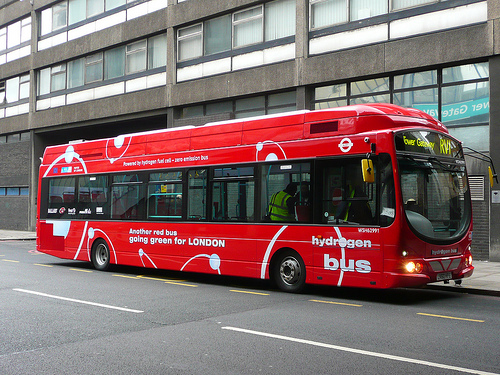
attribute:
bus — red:
[33, 115, 413, 199]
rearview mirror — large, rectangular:
[359, 156, 376, 185]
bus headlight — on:
[402, 258, 418, 274]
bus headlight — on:
[466, 254, 472, 264]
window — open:
[0, 79, 7, 105]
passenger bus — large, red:
[35, 102, 473, 291]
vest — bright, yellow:
[267, 188, 293, 221]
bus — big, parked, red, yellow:
[34, 103, 474, 293]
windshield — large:
[395, 150, 471, 242]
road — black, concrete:
[2, 240, 498, 371]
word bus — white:
[321, 251, 371, 275]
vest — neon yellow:
[266, 191, 293, 219]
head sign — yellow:
[395, 129, 464, 160]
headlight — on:
[402, 259, 418, 276]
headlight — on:
[465, 251, 474, 266]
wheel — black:
[272, 249, 306, 294]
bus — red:
[28, 92, 483, 288]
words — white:
[125, 220, 377, 276]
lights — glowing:
[397, 251, 482, 282]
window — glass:
[308, 143, 444, 233]